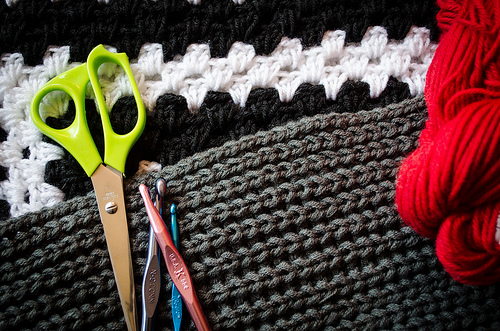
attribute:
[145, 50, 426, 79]
yarn — crocheted, white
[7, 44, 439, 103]
design — jagged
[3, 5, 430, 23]
yarn — crocheted, black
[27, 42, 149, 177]
handle — yellow, cracked, plastic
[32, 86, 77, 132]
fingerhole — round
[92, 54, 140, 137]
fingerhole — oval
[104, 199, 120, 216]
screw — standard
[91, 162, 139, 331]
blades — metal, shiny, pointy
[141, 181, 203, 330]
needle — grey, metal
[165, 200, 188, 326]
needle — metal, blue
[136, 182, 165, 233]
end — big, blunt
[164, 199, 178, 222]
end — small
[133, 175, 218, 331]
needles — different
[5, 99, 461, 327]
yarn — gray, crocheted, grey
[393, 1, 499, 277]
yarn — red, thin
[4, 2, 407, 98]
crochet work — multicolored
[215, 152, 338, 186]
crochet design — small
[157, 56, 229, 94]
stitching — intricate